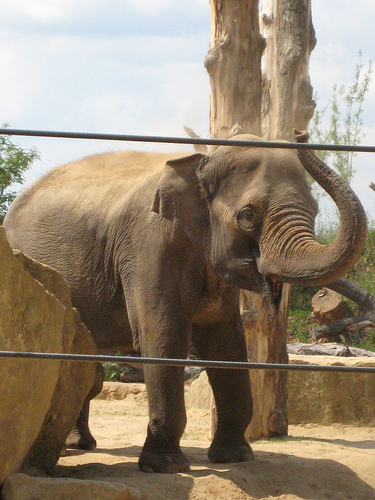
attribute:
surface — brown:
[144, 463, 364, 499]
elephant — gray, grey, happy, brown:
[4, 119, 374, 474]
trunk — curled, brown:
[258, 125, 373, 294]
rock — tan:
[25, 275, 107, 393]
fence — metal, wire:
[7, 129, 374, 164]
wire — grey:
[8, 345, 372, 372]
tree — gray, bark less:
[196, 0, 328, 140]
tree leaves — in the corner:
[3, 147, 35, 183]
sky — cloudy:
[4, 0, 199, 112]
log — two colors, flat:
[306, 312, 374, 344]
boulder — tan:
[299, 357, 372, 412]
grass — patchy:
[366, 265, 374, 287]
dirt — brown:
[104, 406, 140, 469]